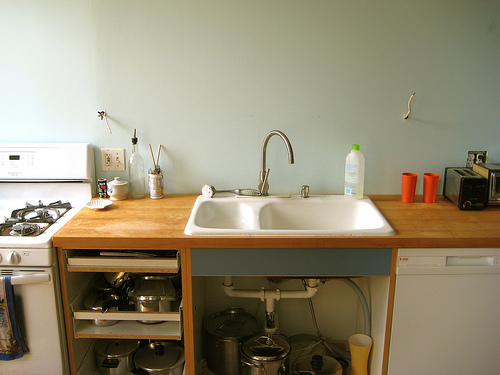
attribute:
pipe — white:
[220, 276, 321, 341]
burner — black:
[7, 197, 76, 222]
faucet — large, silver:
[245, 123, 310, 205]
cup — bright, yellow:
[346, 332, 371, 372]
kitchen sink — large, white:
[187, 192, 391, 237]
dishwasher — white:
[389, 250, 495, 372]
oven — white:
[3, 141, 103, 373]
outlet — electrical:
[96, 140, 135, 178]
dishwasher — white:
[381, 247, 497, 372]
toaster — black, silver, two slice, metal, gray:
[442, 166, 492, 211]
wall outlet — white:
[98, 146, 126, 176]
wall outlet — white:
[462, 147, 488, 167]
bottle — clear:
[340, 144, 369, 204]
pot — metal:
[91, 339, 134, 374]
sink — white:
[181, 187, 394, 244]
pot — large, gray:
[203, 305, 260, 373]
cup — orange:
[400, 171, 418, 203]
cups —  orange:
[399, 169, 440, 203]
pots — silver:
[200, 300, 265, 372]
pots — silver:
[235, 328, 291, 373]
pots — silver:
[285, 349, 342, 370]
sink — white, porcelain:
[182, 184, 398, 239]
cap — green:
[348, 140, 361, 150]